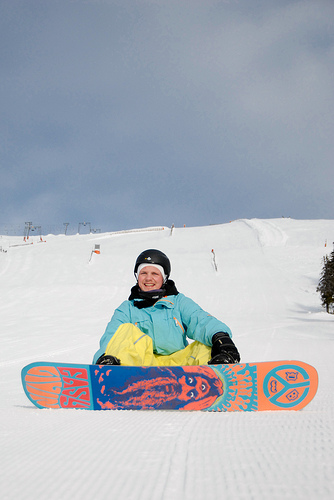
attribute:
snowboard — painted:
[20, 362, 319, 412]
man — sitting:
[92, 247, 241, 364]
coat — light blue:
[96, 301, 230, 368]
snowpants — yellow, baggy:
[107, 322, 209, 366]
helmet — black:
[134, 249, 170, 275]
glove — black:
[209, 333, 238, 365]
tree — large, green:
[317, 250, 332, 311]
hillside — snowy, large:
[2, 216, 333, 500]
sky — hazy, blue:
[1, 2, 333, 235]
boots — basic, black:
[98, 355, 121, 366]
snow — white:
[1, 217, 333, 499]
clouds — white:
[5, 123, 85, 235]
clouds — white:
[162, 1, 333, 195]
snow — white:
[5, 243, 297, 458]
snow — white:
[13, 245, 323, 496]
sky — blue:
[7, 6, 323, 207]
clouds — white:
[217, 41, 315, 190]